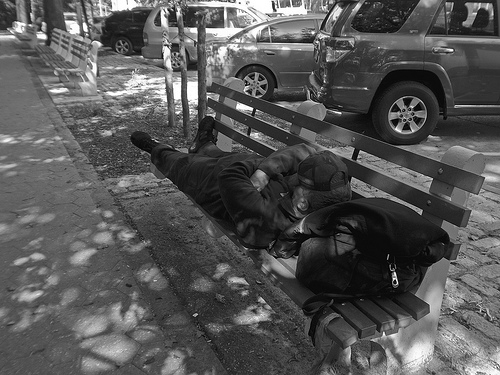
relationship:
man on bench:
[135, 113, 360, 248] [144, 73, 490, 373]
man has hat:
[135, 113, 360, 248] [286, 151, 352, 188]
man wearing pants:
[135, 113, 360, 248] [149, 140, 263, 221]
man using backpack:
[135, 113, 360, 248] [294, 193, 455, 323]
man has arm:
[135, 113, 360, 248] [242, 143, 330, 192]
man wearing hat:
[135, 113, 360, 248] [286, 151, 352, 188]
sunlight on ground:
[80, 303, 154, 361] [15, 36, 499, 366]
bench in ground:
[144, 73, 490, 373] [15, 36, 499, 366]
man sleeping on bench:
[135, 113, 360, 248] [144, 73, 490, 373]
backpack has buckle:
[294, 193, 455, 323] [386, 258, 402, 290]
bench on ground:
[144, 73, 490, 373] [15, 36, 499, 366]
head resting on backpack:
[287, 150, 353, 220] [294, 193, 455, 323]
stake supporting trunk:
[168, 29, 180, 48] [156, 2, 199, 146]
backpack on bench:
[294, 193, 455, 323] [144, 73, 490, 373]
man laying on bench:
[135, 113, 360, 248] [144, 73, 490, 373]